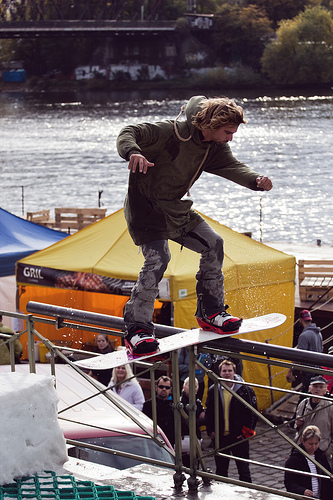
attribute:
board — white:
[67, 311, 286, 372]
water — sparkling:
[261, 142, 304, 187]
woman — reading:
[287, 418, 332, 497]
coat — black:
[284, 444, 331, 495]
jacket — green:
[114, 91, 266, 248]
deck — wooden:
[259, 241, 332, 310]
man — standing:
[149, 367, 181, 427]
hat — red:
[295, 308, 313, 324]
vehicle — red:
[1, 356, 194, 495]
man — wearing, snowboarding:
[115, 95, 273, 353]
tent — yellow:
[18, 196, 294, 407]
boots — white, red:
[111, 298, 235, 365]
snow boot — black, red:
[120, 315, 160, 355]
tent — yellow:
[12, 190, 330, 386]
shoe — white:
[120, 323, 159, 356]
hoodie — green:
[112, 95, 256, 247]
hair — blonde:
[185, 91, 246, 130]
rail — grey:
[25, 298, 323, 364]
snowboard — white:
[67, 311, 290, 372]